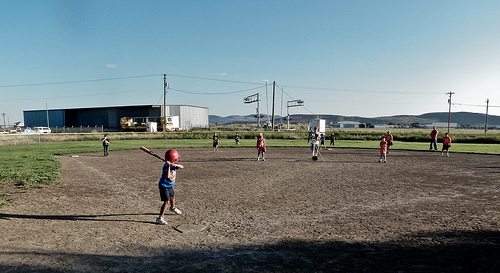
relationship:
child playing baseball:
[156, 148, 183, 225] [99, 125, 452, 262]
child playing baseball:
[156, 148, 183, 225] [70, 125, 482, 256]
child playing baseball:
[156, 148, 183, 225] [75, 125, 481, 270]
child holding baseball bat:
[156, 147, 185, 185] [132, 133, 176, 174]